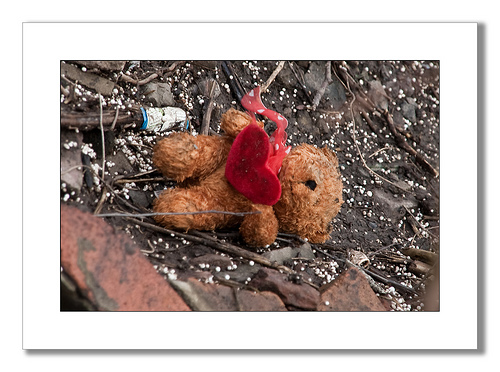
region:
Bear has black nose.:
[297, 168, 313, 203]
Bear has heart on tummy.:
[221, 99, 319, 260]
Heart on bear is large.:
[220, 122, 320, 258]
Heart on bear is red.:
[225, 117, 331, 295]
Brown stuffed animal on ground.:
[138, 72, 364, 246]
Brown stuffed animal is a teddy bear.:
[134, 105, 385, 266]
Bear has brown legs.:
[162, 172, 196, 253]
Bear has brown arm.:
[240, 206, 304, 273]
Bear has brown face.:
[296, 132, 330, 203]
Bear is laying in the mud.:
[139, 107, 434, 278]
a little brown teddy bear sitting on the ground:
[144, 111, 341, 257]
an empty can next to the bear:
[133, 107, 190, 133]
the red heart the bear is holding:
[220, 125, 283, 204]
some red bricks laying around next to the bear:
[56, 215, 391, 327]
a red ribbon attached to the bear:
[235, 85, 295, 171]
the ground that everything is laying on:
[62, 63, 444, 281]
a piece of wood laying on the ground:
[61, 107, 152, 132]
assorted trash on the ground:
[301, 82, 427, 162]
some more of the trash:
[62, 145, 143, 222]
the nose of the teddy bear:
[303, 177, 319, 192]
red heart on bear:
[223, 119, 284, 213]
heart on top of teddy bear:
[225, 111, 288, 225]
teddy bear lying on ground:
[150, 127, 368, 259]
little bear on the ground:
[146, 111, 346, 266]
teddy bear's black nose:
[307, 179, 318, 191]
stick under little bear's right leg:
[119, 191, 282, 276]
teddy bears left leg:
[150, 183, 220, 229]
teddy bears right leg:
[150, 120, 220, 173]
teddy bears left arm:
[241, 206, 288, 257]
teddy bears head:
[280, 124, 347, 257]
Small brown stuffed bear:
[154, 112, 343, 240]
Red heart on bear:
[224, 123, 281, 204]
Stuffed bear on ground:
[151, 104, 355, 244]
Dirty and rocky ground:
[64, 70, 429, 304]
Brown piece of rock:
[60, 214, 178, 313]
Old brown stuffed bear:
[153, 102, 334, 244]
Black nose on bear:
[305, 171, 316, 192]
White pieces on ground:
[343, 66, 433, 306]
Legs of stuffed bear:
[151, 135, 211, 225]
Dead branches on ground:
[62, 107, 149, 222]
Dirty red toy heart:
[222, 118, 284, 201]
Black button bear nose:
[300, 173, 320, 194]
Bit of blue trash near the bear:
[137, 104, 194, 136]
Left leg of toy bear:
[155, 185, 214, 235]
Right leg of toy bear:
[151, 133, 226, 183]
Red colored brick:
[60, 201, 182, 311]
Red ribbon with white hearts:
[237, 85, 295, 152]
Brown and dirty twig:
[125, 208, 278, 270]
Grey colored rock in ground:
[258, 238, 315, 267]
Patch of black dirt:
[336, 199, 393, 249]